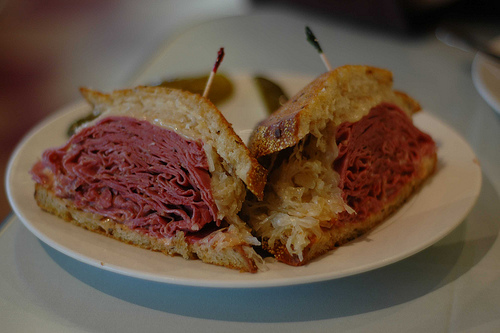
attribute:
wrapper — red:
[212, 47, 226, 80]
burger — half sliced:
[66, 94, 258, 273]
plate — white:
[471, 36, 499, 116]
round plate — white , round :
[11, 70, 482, 302]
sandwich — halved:
[30, 56, 440, 274]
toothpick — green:
[303, 22, 335, 84]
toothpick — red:
[203, 43, 227, 98]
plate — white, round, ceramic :
[5, 68, 484, 290]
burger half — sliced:
[250, 62, 443, 262]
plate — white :
[18, 32, 496, 297]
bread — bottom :
[23, 174, 253, 272]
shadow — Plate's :
[53, 212, 490, 308]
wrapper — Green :
[297, 16, 327, 57]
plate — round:
[8, 50, 474, 287]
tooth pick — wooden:
[162, 54, 227, 98]